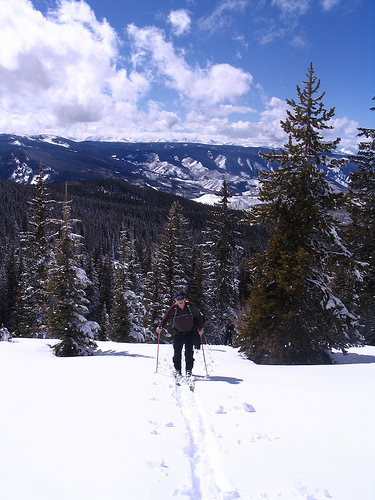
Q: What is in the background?
A: Mountains.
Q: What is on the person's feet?
A: Skis.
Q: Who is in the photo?
A: A woman.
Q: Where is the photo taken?
A: On a mountain.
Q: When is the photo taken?
A: Daytime.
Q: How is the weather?
A: Sunny.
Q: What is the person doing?
A: Skiing.